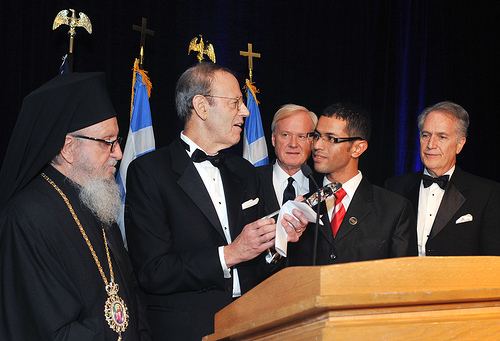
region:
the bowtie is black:
[415, 174, 452, 190]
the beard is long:
[79, 175, 128, 212]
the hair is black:
[327, 103, 378, 139]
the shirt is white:
[419, 188, 434, 232]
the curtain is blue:
[273, 10, 478, 82]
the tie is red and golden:
[322, 195, 346, 220]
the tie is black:
[282, 176, 299, 196]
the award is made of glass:
[282, 181, 342, 214]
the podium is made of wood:
[226, 262, 487, 339]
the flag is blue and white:
[132, 80, 162, 159]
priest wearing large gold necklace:
[38, 170, 131, 340]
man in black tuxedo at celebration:
[123, 52, 320, 336]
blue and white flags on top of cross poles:
[116, 33, 269, 219]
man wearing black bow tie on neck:
[175, 128, 228, 178]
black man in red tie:
[281, 95, 423, 269]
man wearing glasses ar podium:
[119, 66, 346, 336]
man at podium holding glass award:
[121, 55, 348, 337]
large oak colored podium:
[201, 236, 499, 338]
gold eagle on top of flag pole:
[48, 3, 98, 50]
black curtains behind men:
[7, 4, 497, 334]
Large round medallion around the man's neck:
[101, 281, 130, 335]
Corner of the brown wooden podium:
[290, 281, 360, 340]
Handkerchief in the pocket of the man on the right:
[450, 211, 482, 226]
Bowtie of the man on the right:
[418, 168, 455, 191]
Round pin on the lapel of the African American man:
[344, 215, 362, 229]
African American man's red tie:
[327, 182, 347, 237]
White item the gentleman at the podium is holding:
[270, 192, 319, 255]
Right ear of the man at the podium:
[186, 89, 217, 124]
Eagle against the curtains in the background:
[46, 3, 95, 41]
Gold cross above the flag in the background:
[233, 34, 267, 79]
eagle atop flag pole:
[46, 3, 100, 40]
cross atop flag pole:
[235, 38, 265, 82]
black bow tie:
[173, 131, 230, 174]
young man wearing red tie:
[290, 104, 420, 261]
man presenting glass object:
[132, 59, 302, 338]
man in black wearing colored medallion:
[3, 61, 153, 339]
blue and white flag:
[118, 55, 156, 219]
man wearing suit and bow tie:
[371, 94, 497, 261]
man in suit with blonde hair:
[248, 95, 325, 221]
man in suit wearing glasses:
[128, 65, 290, 334]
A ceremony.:
[20, 16, 486, 326]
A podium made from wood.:
[200, 235, 495, 335]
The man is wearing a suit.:
[385, 85, 495, 247]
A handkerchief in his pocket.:
[445, 210, 475, 240]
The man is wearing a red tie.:
[325, 185, 350, 240]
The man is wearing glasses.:
[301, 105, 371, 192]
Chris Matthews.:
[255, 97, 312, 207]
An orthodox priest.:
[6, 85, 153, 335]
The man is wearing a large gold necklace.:
[32, 171, 162, 333]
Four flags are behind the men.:
[45, 40, 293, 221]